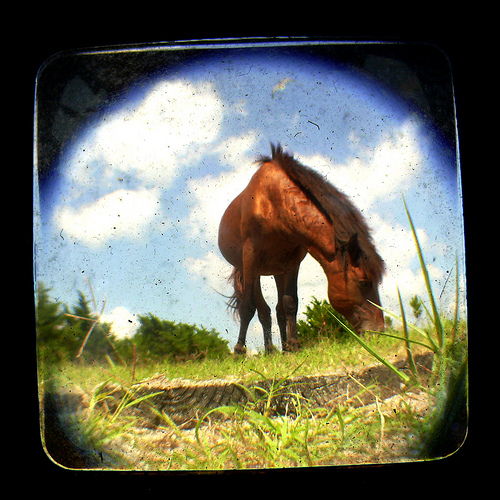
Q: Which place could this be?
A: It is a field.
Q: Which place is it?
A: It is a field.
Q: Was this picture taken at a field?
A: Yes, it was taken in a field.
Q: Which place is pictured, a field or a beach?
A: It is a field.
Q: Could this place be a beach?
A: No, it is a field.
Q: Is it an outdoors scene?
A: Yes, it is outdoors.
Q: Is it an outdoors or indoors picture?
A: It is outdoors.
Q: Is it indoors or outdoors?
A: It is outdoors.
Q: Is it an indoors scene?
A: No, it is outdoors.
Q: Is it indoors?
A: No, it is outdoors.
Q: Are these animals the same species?
A: No, they are horses and birds.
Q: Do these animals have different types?
A: Yes, they are horses and birds.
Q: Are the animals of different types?
A: Yes, they are horses and birds.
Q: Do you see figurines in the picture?
A: No, there are no figurines.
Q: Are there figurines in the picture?
A: No, there are no figurines.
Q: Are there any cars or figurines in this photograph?
A: No, there are no figurines or cars.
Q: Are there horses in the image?
A: Yes, there is a horse.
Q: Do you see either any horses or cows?
A: Yes, there is a horse.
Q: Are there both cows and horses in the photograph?
A: No, there is a horse but no cows.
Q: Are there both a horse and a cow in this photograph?
A: No, there is a horse but no cows.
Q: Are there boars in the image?
A: No, there are no boars.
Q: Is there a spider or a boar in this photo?
A: No, there are no boars or spiders.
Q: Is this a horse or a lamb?
A: This is a horse.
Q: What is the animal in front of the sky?
A: The animal is a horse.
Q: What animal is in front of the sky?
A: The animal is a horse.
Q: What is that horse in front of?
A: The horse is in front of the sky.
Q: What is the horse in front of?
A: The horse is in front of the sky.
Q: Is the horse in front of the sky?
A: Yes, the horse is in front of the sky.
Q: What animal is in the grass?
A: The horse is in the grass.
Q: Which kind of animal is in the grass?
A: The animal is a horse.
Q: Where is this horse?
A: The horse is in the grass.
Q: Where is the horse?
A: The horse is in the grass.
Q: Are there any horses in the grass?
A: Yes, there is a horse in the grass.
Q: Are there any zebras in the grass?
A: No, there is a horse in the grass.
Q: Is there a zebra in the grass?
A: No, there is a horse in the grass.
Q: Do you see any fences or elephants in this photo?
A: No, there are no fences or elephants.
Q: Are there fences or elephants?
A: No, there are no fences or elephants.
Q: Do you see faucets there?
A: No, there are no faucets.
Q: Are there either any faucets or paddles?
A: No, there are no faucets or paddles.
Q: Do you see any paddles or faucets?
A: No, there are no faucets or paddles.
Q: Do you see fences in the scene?
A: No, there are no fences.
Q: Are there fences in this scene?
A: No, there are no fences.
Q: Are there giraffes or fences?
A: No, there are no fences or giraffes.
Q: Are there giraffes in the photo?
A: No, there are no giraffes.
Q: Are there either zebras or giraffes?
A: No, there are no giraffes or zebras.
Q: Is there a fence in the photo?
A: No, there are no fences.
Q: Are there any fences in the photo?
A: No, there are no fences.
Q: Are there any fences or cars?
A: No, there are no fences or cars.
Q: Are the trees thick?
A: Yes, the trees are thick.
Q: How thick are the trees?
A: The trees are thick.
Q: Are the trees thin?
A: No, the trees are thick.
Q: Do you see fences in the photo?
A: No, there are no fences.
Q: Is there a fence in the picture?
A: No, there are no fences.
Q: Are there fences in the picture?
A: No, there are no fences.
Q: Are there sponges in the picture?
A: No, there are no sponges.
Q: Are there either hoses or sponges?
A: No, there are no sponges or hoses.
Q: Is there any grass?
A: Yes, there is grass.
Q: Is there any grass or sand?
A: Yes, there is grass.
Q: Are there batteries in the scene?
A: No, there are no batteries.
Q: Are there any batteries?
A: No, there are no batteries.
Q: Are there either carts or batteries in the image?
A: No, there are no batteries or carts.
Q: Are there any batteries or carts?
A: No, there are no batteries or carts.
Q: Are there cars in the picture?
A: No, there are no cars.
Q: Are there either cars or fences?
A: No, there are no cars or fences.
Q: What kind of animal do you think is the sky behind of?
A: The sky is behind the horse.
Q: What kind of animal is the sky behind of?
A: The sky is behind the horse.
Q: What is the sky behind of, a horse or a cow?
A: The sky is behind a horse.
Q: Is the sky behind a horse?
A: Yes, the sky is behind a horse.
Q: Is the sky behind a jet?
A: No, the sky is behind a horse.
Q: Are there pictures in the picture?
A: No, there are no pictures.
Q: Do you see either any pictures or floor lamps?
A: No, there are no pictures or floor lamps.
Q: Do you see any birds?
A: Yes, there is a bird.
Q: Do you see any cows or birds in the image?
A: Yes, there is a bird.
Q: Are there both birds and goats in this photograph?
A: No, there is a bird but no goats.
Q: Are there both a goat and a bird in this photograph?
A: No, there is a bird but no goats.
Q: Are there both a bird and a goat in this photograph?
A: No, there is a bird but no goats.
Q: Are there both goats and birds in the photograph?
A: No, there is a bird but no goats.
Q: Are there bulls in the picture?
A: No, there are no bulls.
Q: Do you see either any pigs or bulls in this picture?
A: No, there are no bulls or pigs.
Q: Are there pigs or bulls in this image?
A: No, there are no bulls or pigs.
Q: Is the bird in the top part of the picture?
A: Yes, the bird is in the top of the image.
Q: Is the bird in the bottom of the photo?
A: No, the bird is in the top of the image.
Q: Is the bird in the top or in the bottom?
A: The bird is in the top of the image.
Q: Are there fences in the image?
A: No, there are no fences.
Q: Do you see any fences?
A: No, there are no fences.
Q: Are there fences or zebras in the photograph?
A: No, there are no fences or zebras.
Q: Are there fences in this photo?
A: No, there are no fences.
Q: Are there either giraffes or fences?
A: No, there are no fences or giraffes.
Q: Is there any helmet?
A: No, there are no helmets.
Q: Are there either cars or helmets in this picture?
A: No, there are no helmets or cars.